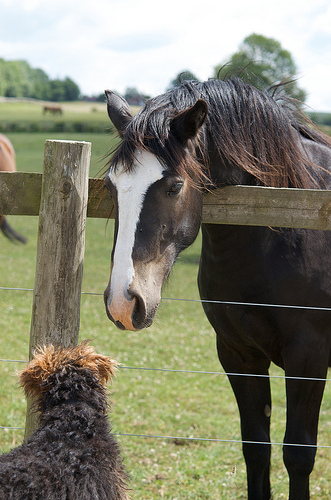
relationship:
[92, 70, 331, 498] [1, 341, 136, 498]
horse examining dog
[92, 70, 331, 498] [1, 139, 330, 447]
horse over fence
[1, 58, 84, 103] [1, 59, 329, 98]
trees on distance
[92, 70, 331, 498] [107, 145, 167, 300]
horse has stripe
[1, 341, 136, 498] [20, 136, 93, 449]
dog next pole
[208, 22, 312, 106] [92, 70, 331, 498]
tree behind horse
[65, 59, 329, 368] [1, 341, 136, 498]
horse looks down at dog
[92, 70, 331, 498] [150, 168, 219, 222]
horse has eye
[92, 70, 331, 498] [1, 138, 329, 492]
horse behind fence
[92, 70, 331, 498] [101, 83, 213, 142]
horse has ears